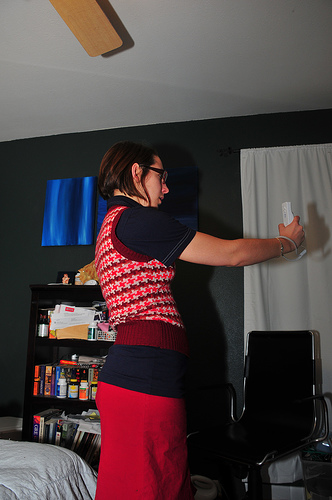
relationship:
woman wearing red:
[80, 140, 194, 499] [129, 408, 134, 413]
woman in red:
[80, 140, 194, 499] [129, 408, 134, 413]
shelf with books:
[34, 283, 44, 293] [36, 359, 54, 391]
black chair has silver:
[221, 330, 324, 472] [307, 390, 331, 434]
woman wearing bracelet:
[80, 140, 194, 499] [267, 236, 294, 270]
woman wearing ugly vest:
[80, 140, 194, 499] [91, 212, 183, 328]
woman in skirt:
[80, 140, 194, 499] [89, 365, 199, 481]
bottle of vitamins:
[65, 377, 83, 409] [75, 395, 77, 397]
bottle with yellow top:
[65, 377, 83, 409] [65, 372, 83, 383]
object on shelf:
[52, 321, 98, 346] [34, 283, 44, 293]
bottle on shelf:
[65, 377, 83, 409] [34, 283, 44, 293]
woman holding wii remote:
[80, 140, 194, 499] [262, 193, 300, 253]